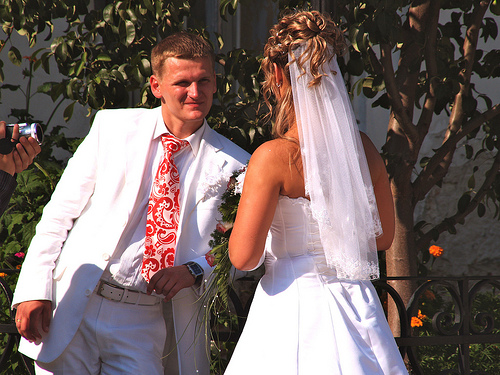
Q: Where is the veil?
A: On the woman.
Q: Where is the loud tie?
A: On the man.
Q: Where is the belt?
A: On the man.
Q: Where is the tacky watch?
A: On the man.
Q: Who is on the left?
A: The groom.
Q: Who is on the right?
A: The bride.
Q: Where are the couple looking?
A: At each other.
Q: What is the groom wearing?
A: White with a patterned tie.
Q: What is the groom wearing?
A: White with a red and white tie.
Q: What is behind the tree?
A: A white wall.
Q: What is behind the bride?
A: A black iron fence.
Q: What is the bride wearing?
A: A wedding gown.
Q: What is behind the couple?
A: A black iron fence.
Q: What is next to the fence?
A: A large tree.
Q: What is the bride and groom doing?
A: They are looking at each other.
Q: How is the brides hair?
A: The brides hair is half up and half down.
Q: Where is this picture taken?
A: Wedding.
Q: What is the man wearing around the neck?
A: A tie.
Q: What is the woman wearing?
A: A wedding dress.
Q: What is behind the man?
A: A tree.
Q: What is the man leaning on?
A: A fence.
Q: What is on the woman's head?
A: A veil.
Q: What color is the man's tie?
A: Red and white.